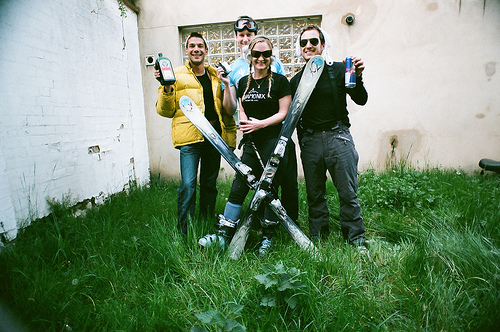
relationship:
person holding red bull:
[292, 26, 379, 255] [342, 56, 356, 88]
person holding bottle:
[221, 14, 301, 224] [219, 55, 234, 74]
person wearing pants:
[292, 26, 379, 255] [299, 125, 369, 246]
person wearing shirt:
[292, 26, 379, 255] [287, 58, 367, 136]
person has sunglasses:
[292, 26, 379, 255] [299, 38, 325, 47]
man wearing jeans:
[152, 32, 236, 232] [174, 143, 223, 240]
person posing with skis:
[292, 26, 379, 255] [178, 95, 316, 252]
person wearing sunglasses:
[292, 26, 379, 255] [299, 38, 325, 47]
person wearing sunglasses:
[195, 31, 300, 257] [249, 49, 274, 60]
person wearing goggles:
[221, 14, 301, 224] [234, 19, 256, 35]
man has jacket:
[152, 32, 236, 232] [154, 62, 238, 151]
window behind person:
[176, 14, 325, 82] [292, 26, 379, 255]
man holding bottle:
[152, 32, 236, 232] [152, 52, 175, 85]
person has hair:
[195, 31, 300, 257] [239, 37, 273, 100]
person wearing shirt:
[221, 14, 301, 224] [221, 56, 285, 91]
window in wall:
[176, 14, 325, 82] [137, 1, 499, 182]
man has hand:
[152, 32, 236, 232] [155, 70, 173, 92]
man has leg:
[152, 32, 236, 232] [177, 145, 200, 234]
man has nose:
[152, 32, 236, 232] [194, 47, 201, 52]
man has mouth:
[152, 32, 236, 232] [191, 52, 204, 59]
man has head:
[152, 32, 236, 232] [181, 32, 207, 67]